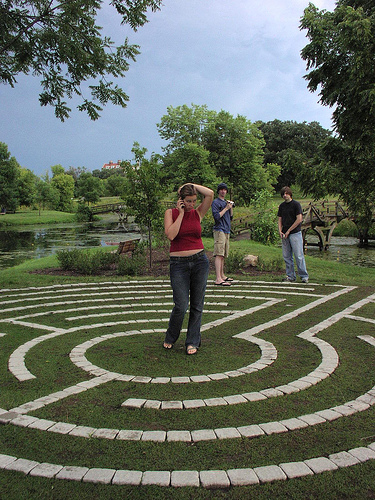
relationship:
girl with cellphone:
[160, 183, 214, 357] [180, 198, 185, 210]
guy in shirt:
[211, 181, 235, 285] [212, 197, 237, 232]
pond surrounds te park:
[6, 151, 350, 196] [8, 162, 373, 272]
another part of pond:
[4, 155, 373, 498] [6, 151, 350, 196]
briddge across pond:
[228, 205, 319, 236] [6, 151, 350, 196]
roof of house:
[102, 158, 126, 165] [104, 153, 138, 178]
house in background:
[104, 153, 138, 178] [7, 80, 374, 192]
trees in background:
[2, 140, 335, 184] [7, 80, 374, 192]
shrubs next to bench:
[56, 242, 122, 269] [107, 235, 141, 257]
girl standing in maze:
[160, 183, 214, 357] [8, 276, 370, 482]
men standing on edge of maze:
[216, 182, 315, 282] [45, 230, 374, 278]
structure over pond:
[271, 188, 353, 250] [0, 195, 375, 271]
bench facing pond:
[115, 227, 144, 254] [0, 195, 375, 271]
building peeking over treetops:
[105, 158, 126, 166] [75, 162, 143, 187]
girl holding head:
[160, 183, 214, 357] [176, 190, 201, 208]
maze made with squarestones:
[43, 280, 371, 365] [295, 379, 310, 390]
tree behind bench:
[311, 20, 372, 195] [115, 227, 144, 254]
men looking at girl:
[216, 182, 315, 282] [160, 183, 214, 357]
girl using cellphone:
[160, 183, 214, 357] [180, 198, 185, 210]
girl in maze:
[160, 183, 214, 357] [43, 280, 371, 365]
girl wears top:
[160, 183, 214, 357] [166, 212, 210, 252]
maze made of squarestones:
[43, 280, 371, 365] [295, 379, 310, 390]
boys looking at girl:
[216, 182, 315, 282] [160, 183, 214, 357]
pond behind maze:
[6, 151, 350, 196] [43, 280, 371, 365]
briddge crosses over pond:
[83, 199, 172, 219] [6, 151, 350, 196]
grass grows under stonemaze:
[56, 242, 122, 269] [8, 276, 370, 482]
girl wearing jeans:
[160, 183, 214, 357] [163, 257, 203, 349]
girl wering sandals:
[160, 183, 214, 357] [160, 331, 202, 354]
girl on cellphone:
[149, 203, 226, 357] [171, 195, 192, 213]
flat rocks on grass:
[240, 252, 263, 269] [26, 246, 108, 261]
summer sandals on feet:
[159, 338, 211, 354] [149, 203, 226, 357]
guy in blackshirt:
[278, 185, 309, 286] [275, 204, 304, 235]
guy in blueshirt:
[211, 181, 235, 285] [212, 197, 237, 232]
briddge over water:
[83, 199, 172, 219] [77, 191, 180, 211]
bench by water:
[117, 237, 139, 254] [77, 191, 180, 211]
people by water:
[148, 181, 307, 349] [21, 227, 122, 243]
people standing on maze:
[148, 181, 307, 349] [43, 280, 371, 365]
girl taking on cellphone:
[149, 203, 226, 357] [180, 198, 185, 210]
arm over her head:
[175, 181, 220, 215] [176, 190, 201, 208]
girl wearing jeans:
[149, 203, 226, 357] [163, 257, 203, 349]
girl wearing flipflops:
[149, 203, 226, 357] [160, 334, 207, 361]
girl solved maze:
[149, 203, 226, 357] [43, 280, 371, 365]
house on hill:
[104, 153, 138, 178] [75, 168, 328, 190]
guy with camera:
[211, 181, 248, 290] [223, 198, 237, 206]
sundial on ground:
[8, 276, 370, 482] [3, 236, 373, 497]